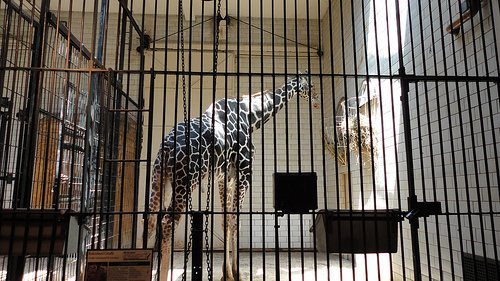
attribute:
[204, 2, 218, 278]
chain — long, black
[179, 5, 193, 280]
chain — black, long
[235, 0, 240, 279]
bar — thin, metal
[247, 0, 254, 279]
bar — metal, thin